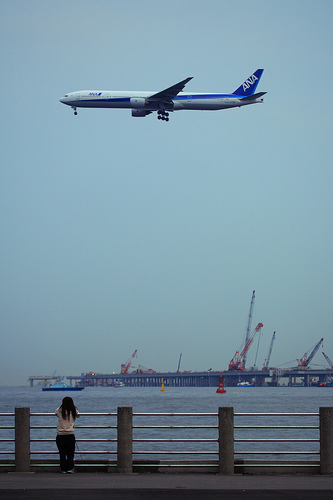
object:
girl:
[55, 396, 79, 476]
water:
[0, 388, 333, 464]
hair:
[59, 396, 78, 422]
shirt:
[55, 405, 81, 435]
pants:
[55, 434, 75, 472]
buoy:
[216, 371, 226, 393]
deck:
[30, 371, 328, 387]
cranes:
[176, 353, 182, 373]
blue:
[0, 0, 333, 362]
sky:
[0, 0, 333, 366]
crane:
[228, 323, 264, 371]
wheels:
[157, 110, 169, 122]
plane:
[59, 69, 267, 122]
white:
[59, 89, 264, 110]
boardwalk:
[0, 469, 333, 500]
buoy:
[160, 377, 165, 391]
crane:
[121, 350, 138, 375]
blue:
[68, 68, 264, 103]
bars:
[0, 412, 332, 464]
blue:
[42, 376, 85, 391]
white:
[56, 379, 68, 388]